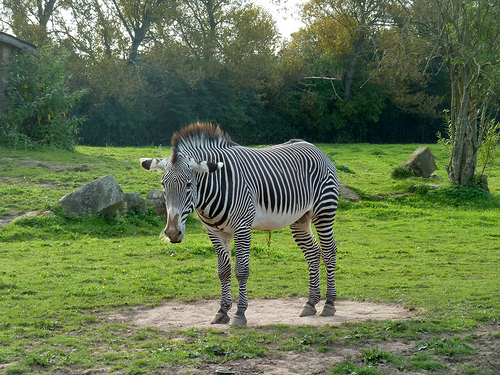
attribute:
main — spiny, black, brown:
[167, 124, 245, 161]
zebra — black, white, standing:
[146, 120, 362, 329]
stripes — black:
[251, 148, 302, 211]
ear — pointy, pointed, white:
[138, 155, 165, 173]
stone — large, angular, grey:
[57, 175, 136, 231]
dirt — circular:
[139, 284, 418, 336]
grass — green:
[38, 235, 178, 302]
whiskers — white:
[155, 231, 170, 248]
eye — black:
[187, 181, 191, 191]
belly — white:
[256, 212, 312, 233]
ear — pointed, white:
[189, 156, 226, 175]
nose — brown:
[161, 222, 191, 247]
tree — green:
[179, 3, 240, 132]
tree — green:
[100, 2, 190, 140]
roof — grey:
[1, 29, 39, 57]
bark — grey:
[457, 122, 474, 162]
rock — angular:
[402, 143, 439, 184]